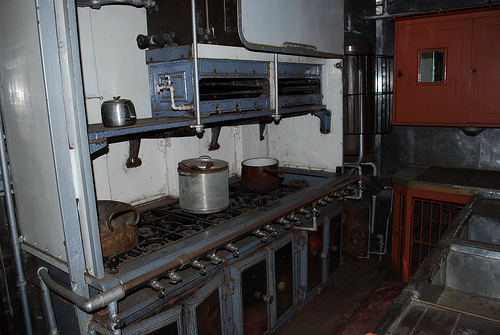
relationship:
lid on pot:
[178, 152, 228, 169] [178, 153, 230, 213]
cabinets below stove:
[118, 235, 353, 333] [103, 162, 312, 250]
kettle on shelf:
[95, 86, 149, 137] [87, 113, 201, 137]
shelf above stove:
[82, 111, 209, 152] [85, 174, 357, 330]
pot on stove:
[176, 153, 232, 215] [86, 177, 358, 312]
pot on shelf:
[100, 90, 140, 130] [80, 109, 197, 151]